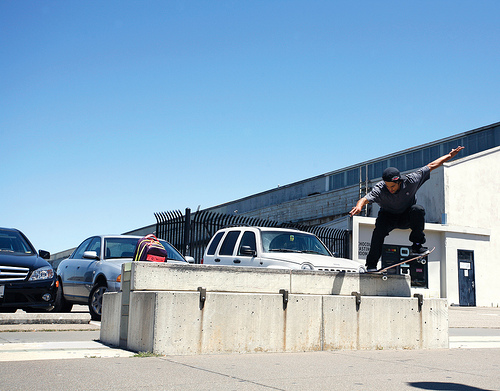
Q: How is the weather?
A: It is clear.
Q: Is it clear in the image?
A: Yes, it is clear.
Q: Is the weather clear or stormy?
A: It is clear.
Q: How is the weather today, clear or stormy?
A: It is clear.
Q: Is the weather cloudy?
A: No, it is clear.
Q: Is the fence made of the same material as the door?
A: Yes, both the fence and the door are made of metal.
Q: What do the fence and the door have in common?
A: The material, both the fence and the door are metallic.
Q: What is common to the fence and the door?
A: The material, both the fence and the door are metallic.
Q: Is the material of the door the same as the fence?
A: Yes, both the door and the fence are made of metal.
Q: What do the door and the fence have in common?
A: The material, both the door and the fence are metallic.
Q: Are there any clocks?
A: No, there are no clocks.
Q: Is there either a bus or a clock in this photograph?
A: No, there are no clocks or buses.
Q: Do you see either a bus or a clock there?
A: No, there are no clocks or buses.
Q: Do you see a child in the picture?
A: No, there are no children.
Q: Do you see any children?
A: No, there are no children.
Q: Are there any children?
A: No, there are no children.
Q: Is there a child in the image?
A: No, there are no children.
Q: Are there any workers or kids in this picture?
A: No, there are no kids or workers.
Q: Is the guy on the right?
A: Yes, the guy is on the right of the image.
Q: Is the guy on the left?
A: No, the guy is on the right of the image.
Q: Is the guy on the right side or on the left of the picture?
A: The guy is on the right of the image.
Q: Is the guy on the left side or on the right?
A: The guy is on the right of the image.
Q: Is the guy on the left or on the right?
A: The guy is on the right of the image.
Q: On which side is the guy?
A: The guy is on the right of the image.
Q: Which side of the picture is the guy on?
A: The guy is on the right of the image.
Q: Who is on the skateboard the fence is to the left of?
A: The guy is on the skateboard.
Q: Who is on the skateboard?
A: The guy is on the skateboard.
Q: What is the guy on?
A: The guy is on the skateboard.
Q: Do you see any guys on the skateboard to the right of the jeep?
A: Yes, there is a guy on the skateboard.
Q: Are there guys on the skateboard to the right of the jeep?
A: Yes, there is a guy on the skateboard.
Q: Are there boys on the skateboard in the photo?
A: No, there is a guy on the skateboard.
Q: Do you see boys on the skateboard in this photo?
A: No, there is a guy on the skateboard.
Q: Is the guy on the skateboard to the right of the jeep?
A: Yes, the guy is on the skateboard.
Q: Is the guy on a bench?
A: No, the guy is on the skateboard.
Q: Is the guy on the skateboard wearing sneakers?
A: Yes, the guy is wearing sneakers.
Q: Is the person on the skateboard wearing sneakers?
A: Yes, the guy is wearing sneakers.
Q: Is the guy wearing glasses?
A: No, the guy is wearing sneakers.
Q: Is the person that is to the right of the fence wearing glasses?
A: No, the guy is wearing sneakers.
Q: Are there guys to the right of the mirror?
A: Yes, there is a guy to the right of the mirror.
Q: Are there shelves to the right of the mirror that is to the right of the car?
A: No, there is a guy to the right of the mirror.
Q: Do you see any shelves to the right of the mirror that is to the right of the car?
A: No, there is a guy to the right of the mirror.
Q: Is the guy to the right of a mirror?
A: Yes, the guy is to the right of a mirror.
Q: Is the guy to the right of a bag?
A: No, the guy is to the right of a mirror.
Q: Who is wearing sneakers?
A: The guy is wearing sneakers.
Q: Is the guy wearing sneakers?
A: Yes, the guy is wearing sneakers.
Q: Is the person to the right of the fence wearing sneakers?
A: Yes, the guy is wearing sneakers.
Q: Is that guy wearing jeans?
A: No, the guy is wearing sneakers.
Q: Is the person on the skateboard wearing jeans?
A: No, the guy is wearing sneakers.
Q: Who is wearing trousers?
A: The guy is wearing trousers.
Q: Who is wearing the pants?
A: The guy is wearing trousers.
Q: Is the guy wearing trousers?
A: Yes, the guy is wearing trousers.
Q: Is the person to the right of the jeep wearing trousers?
A: Yes, the guy is wearing trousers.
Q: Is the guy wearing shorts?
A: No, the guy is wearing trousers.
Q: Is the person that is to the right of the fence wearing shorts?
A: No, the guy is wearing trousers.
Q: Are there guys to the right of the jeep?
A: Yes, there is a guy to the right of the jeep.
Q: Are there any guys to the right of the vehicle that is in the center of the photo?
A: Yes, there is a guy to the right of the jeep.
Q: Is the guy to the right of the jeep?
A: Yes, the guy is to the right of the jeep.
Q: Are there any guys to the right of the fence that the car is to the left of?
A: Yes, there is a guy to the right of the fence.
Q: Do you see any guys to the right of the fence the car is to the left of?
A: Yes, there is a guy to the right of the fence.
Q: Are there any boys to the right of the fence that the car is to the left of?
A: No, there is a guy to the right of the fence.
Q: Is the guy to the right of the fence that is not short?
A: Yes, the guy is to the right of the fence.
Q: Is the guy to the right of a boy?
A: No, the guy is to the right of the fence.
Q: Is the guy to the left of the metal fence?
A: No, the guy is to the right of the fence.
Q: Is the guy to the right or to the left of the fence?
A: The guy is to the right of the fence.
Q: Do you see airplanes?
A: No, there are no airplanes.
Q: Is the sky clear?
A: Yes, the sky is clear.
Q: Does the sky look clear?
A: Yes, the sky is clear.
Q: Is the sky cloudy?
A: No, the sky is clear.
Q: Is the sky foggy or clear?
A: The sky is clear.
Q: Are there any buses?
A: No, there are no buses.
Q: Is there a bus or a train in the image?
A: No, there are no buses or trains.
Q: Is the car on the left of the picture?
A: Yes, the car is on the left of the image.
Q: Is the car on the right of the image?
A: No, the car is on the left of the image.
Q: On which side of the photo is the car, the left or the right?
A: The car is on the left of the image.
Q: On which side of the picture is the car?
A: The car is on the left of the image.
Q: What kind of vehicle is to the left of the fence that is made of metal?
A: The vehicle is a car.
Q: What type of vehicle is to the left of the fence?
A: The vehicle is a car.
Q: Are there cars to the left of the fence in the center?
A: Yes, there is a car to the left of the fence.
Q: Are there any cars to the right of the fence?
A: No, the car is to the left of the fence.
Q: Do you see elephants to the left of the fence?
A: No, there is a car to the left of the fence.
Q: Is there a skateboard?
A: Yes, there is a skateboard.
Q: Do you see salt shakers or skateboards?
A: Yes, there is a skateboard.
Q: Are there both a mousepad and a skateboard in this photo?
A: No, there is a skateboard but no mouse pads.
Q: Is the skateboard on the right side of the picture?
A: Yes, the skateboard is on the right of the image.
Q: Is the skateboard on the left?
A: No, the skateboard is on the right of the image.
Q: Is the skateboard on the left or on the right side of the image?
A: The skateboard is on the right of the image.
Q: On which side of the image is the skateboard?
A: The skateboard is on the right of the image.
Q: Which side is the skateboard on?
A: The skateboard is on the right of the image.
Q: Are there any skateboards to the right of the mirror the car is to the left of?
A: Yes, there is a skateboard to the right of the mirror.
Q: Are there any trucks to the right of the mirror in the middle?
A: No, there is a skateboard to the right of the mirror.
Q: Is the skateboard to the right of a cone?
A: No, the skateboard is to the right of the mirror.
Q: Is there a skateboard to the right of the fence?
A: Yes, there is a skateboard to the right of the fence.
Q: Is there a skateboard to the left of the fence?
A: No, the skateboard is to the right of the fence.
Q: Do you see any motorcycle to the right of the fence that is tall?
A: No, there is a skateboard to the right of the fence.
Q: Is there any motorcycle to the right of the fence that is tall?
A: No, there is a skateboard to the right of the fence.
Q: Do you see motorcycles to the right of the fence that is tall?
A: No, there is a skateboard to the right of the fence.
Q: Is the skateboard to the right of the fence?
A: Yes, the skateboard is to the right of the fence.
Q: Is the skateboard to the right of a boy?
A: No, the skateboard is to the right of the fence.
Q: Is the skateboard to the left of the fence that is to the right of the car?
A: No, the skateboard is to the right of the fence.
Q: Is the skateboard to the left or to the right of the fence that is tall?
A: The skateboard is to the right of the fence.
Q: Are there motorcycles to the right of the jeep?
A: No, there is a skateboard to the right of the jeep.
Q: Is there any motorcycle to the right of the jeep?
A: No, there is a skateboard to the right of the jeep.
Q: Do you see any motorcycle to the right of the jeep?
A: No, there is a skateboard to the right of the jeep.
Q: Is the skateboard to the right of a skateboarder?
A: No, the skateboard is to the right of the jeep.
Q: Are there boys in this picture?
A: No, there are no boys.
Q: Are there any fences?
A: Yes, there is a fence.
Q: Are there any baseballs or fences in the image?
A: Yes, there is a fence.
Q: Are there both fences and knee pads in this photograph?
A: No, there is a fence but no knee pads.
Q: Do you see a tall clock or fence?
A: Yes, there is a tall fence.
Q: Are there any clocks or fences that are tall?
A: Yes, the fence is tall.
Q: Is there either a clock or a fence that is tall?
A: Yes, the fence is tall.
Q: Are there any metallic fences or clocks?
A: Yes, there is a metal fence.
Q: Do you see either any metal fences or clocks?
A: Yes, there is a metal fence.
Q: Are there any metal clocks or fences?
A: Yes, there is a metal fence.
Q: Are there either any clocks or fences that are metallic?
A: Yes, the fence is metallic.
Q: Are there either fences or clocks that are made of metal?
A: Yes, the fence is made of metal.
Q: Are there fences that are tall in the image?
A: Yes, there is a tall fence.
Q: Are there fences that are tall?
A: Yes, there is a fence that is tall.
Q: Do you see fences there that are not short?
A: Yes, there is a tall fence.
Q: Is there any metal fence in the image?
A: Yes, there is a metal fence.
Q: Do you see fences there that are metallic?
A: Yes, there is a metal fence.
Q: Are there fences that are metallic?
A: Yes, there is a fence that is metallic.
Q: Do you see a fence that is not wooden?
A: Yes, there is a metallic fence.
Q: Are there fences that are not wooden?
A: Yes, there is a metallic fence.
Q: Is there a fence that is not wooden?
A: Yes, there is a metallic fence.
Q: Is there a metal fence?
A: Yes, there is a fence that is made of metal.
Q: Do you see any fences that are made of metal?
A: Yes, there is a fence that is made of metal.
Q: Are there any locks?
A: No, there are no locks.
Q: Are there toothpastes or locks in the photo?
A: No, there are no locks or toothpastes.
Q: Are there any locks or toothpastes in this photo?
A: No, there are no locks or toothpastes.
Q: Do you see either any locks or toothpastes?
A: No, there are no locks or toothpastes.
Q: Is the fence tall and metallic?
A: Yes, the fence is tall and metallic.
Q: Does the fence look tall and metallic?
A: Yes, the fence is tall and metallic.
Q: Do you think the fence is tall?
A: Yes, the fence is tall.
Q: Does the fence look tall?
A: Yes, the fence is tall.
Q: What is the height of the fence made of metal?
A: The fence is tall.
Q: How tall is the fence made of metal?
A: The fence is tall.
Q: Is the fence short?
A: No, the fence is tall.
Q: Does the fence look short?
A: No, the fence is tall.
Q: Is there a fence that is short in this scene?
A: No, there is a fence but it is tall.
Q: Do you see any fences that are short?
A: No, there is a fence but it is tall.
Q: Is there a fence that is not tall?
A: No, there is a fence but it is tall.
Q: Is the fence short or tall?
A: The fence is tall.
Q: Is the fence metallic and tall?
A: Yes, the fence is metallic and tall.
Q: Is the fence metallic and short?
A: No, the fence is metallic but tall.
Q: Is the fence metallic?
A: Yes, the fence is metallic.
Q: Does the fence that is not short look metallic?
A: Yes, the fence is metallic.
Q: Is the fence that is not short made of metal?
A: Yes, the fence is made of metal.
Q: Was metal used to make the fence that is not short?
A: Yes, the fence is made of metal.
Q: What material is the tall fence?
A: The fence is made of metal.